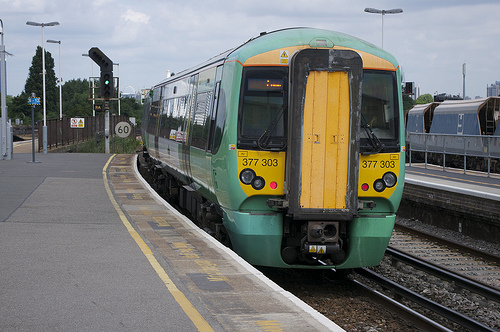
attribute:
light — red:
[82, 54, 130, 107]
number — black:
[360, 160, 369, 170]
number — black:
[367, 157, 372, 169]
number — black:
[370, 157, 377, 171]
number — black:
[378, 159, 385, 170]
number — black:
[384, 159, 391, 169]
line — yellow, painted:
[101, 152, 215, 330]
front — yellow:
[227, 28, 405, 268]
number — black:
[366, 157, 373, 167]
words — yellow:
[166, 225, 241, 313]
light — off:
[213, 161, 291, 196]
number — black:
[249, 153, 262, 167]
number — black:
[370, 157, 380, 169]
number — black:
[347, 149, 427, 184]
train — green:
[186, 29, 429, 328]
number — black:
[240, 155, 282, 169]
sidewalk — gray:
[3, 148, 345, 330]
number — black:
[272, 157, 279, 167]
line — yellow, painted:
[88, 140, 228, 330]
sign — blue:
[26, 87, 41, 107]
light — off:
[362, 4, 403, 17]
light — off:
[24, 18, 60, 28]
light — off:
[238, 166, 255, 187]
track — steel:
[349, 245, 499, 330]